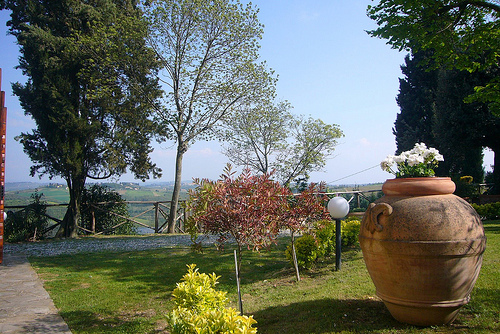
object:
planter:
[359, 176, 482, 326]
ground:
[1, 211, 499, 333]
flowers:
[380, 142, 444, 179]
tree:
[179, 162, 330, 309]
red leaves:
[200, 196, 216, 213]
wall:
[2, 220, 366, 261]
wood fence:
[5, 190, 393, 243]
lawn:
[30, 226, 498, 333]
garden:
[2, 189, 499, 333]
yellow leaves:
[166, 264, 258, 332]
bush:
[165, 264, 258, 333]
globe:
[327, 196, 350, 217]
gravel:
[3, 217, 308, 259]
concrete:
[1, 256, 73, 332]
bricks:
[2, 89, 7, 265]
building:
[1, 81, 6, 266]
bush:
[286, 219, 361, 273]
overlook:
[4, 18, 498, 238]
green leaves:
[477, 1, 499, 17]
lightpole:
[334, 220, 341, 270]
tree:
[2, 1, 171, 240]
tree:
[393, 3, 496, 203]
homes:
[48, 182, 141, 190]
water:
[131, 223, 162, 235]